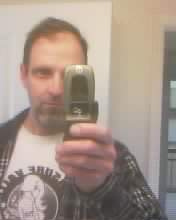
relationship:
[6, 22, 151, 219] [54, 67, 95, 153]
man has cell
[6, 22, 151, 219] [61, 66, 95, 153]
man holds cell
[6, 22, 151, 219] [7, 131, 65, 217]
man wears t-shirt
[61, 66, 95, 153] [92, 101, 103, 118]
cell has antenna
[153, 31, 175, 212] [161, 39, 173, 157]
doorway has edge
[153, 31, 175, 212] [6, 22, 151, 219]
doorway behind man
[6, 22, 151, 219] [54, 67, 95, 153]
man looks at cell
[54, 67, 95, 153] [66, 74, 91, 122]
cell has back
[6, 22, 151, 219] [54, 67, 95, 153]
man uses cell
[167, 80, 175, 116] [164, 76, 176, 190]
windows in room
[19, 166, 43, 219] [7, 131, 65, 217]
character on t-shirt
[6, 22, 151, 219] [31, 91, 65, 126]
man has beard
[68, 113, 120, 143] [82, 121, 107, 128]
finger has edge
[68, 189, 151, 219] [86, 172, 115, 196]
sleeve has edge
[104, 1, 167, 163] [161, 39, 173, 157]
wall has edge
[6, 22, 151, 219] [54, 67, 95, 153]
man holds cell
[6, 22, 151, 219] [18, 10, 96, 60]
man has hair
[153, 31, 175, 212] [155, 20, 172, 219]
doorway to room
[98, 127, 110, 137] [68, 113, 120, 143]
part of finger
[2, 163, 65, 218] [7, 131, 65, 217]
part of t-shirt